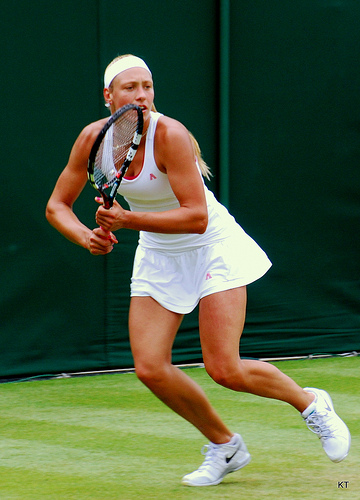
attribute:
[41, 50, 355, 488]
woman — blonde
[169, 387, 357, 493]
shoes — white, laced, black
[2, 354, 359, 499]
court — green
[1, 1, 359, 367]
wall — green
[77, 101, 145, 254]
racket — black, white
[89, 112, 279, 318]
outfit — white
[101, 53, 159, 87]
band — white